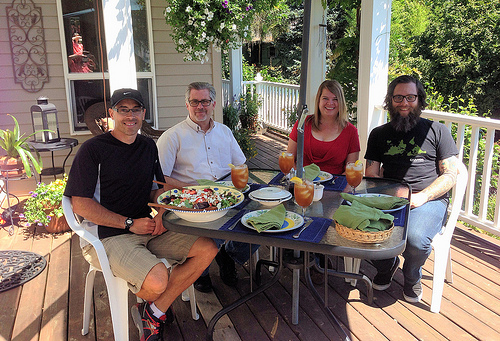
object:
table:
[160, 167, 412, 340]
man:
[363, 74, 459, 304]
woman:
[286, 79, 362, 176]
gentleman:
[154, 81, 247, 183]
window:
[56, 0, 159, 136]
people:
[62, 73, 460, 340]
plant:
[179, 6, 240, 62]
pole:
[295, 103, 310, 177]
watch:
[123, 214, 135, 232]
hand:
[126, 217, 157, 234]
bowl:
[155, 182, 245, 223]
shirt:
[363, 116, 460, 200]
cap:
[110, 88, 147, 109]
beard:
[382, 103, 423, 131]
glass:
[294, 183, 316, 217]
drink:
[231, 169, 249, 189]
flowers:
[167, 1, 215, 27]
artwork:
[4, 0, 51, 94]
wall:
[158, 23, 168, 107]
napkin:
[341, 210, 380, 222]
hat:
[110, 88, 147, 108]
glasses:
[392, 93, 405, 102]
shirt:
[288, 114, 361, 174]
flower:
[214, 16, 239, 42]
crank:
[295, 104, 310, 149]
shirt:
[155, 114, 247, 183]